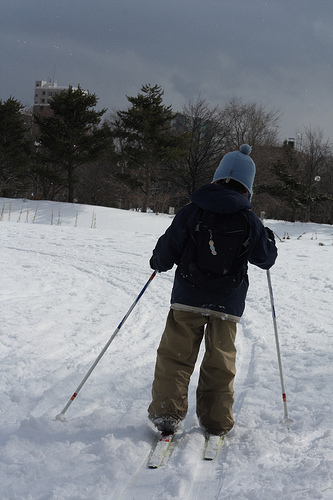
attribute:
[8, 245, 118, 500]
ground — snow-covered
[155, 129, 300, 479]
person — skiing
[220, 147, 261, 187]
hat — blue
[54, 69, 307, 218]
building — in back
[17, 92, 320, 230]
trees — pines, in distance, green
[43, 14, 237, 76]
sky — grey, blue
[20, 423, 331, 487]
snow — white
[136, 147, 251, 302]
jacket — blue, black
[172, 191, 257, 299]
backpack — black